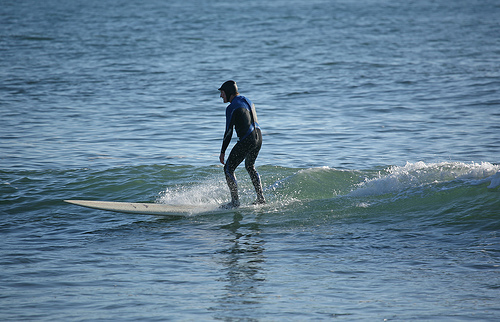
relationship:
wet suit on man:
[212, 77, 273, 208] [212, 74, 270, 209]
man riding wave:
[212, 74, 270, 209] [243, 156, 499, 217]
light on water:
[194, 216, 306, 262] [3, 1, 499, 320]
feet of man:
[216, 195, 268, 210] [212, 74, 270, 209]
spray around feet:
[159, 185, 225, 200] [216, 195, 268, 210]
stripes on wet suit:
[237, 98, 260, 137] [212, 77, 273, 208]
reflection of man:
[217, 209, 266, 295] [212, 74, 270, 209]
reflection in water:
[217, 209, 266, 295] [3, 1, 499, 320]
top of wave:
[390, 157, 497, 188] [243, 156, 499, 217]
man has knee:
[212, 74, 270, 209] [221, 163, 233, 176]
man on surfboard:
[212, 74, 270, 209] [56, 195, 275, 218]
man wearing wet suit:
[212, 74, 270, 209] [212, 77, 273, 208]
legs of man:
[221, 137, 266, 207] [212, 74, 270, 209]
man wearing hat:
[212, 74, 270, 209] [221, 78, 243, 99]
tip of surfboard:
[61, 197, 76, 203] [56, 195, 275, 218]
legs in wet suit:
[221, 137, 266, 207] [212, 77, 273, 208]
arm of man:
[216, 110, 234, 161] [212, 74, 270, 209]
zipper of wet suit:
[244, 97, 256, 119] [212, 77, 273, 208]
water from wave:
[3, 1, 499, 320] [243, 156, 499, 217]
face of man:
[219, 91, 228, 103] [212, 74, 270, 209]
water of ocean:
[3, 1, 499, 320] [3, 2, 479, 184]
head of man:
[215, 77, 240, 106] [212, 74, 270, 209]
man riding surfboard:
[212, 74, 270, 209] [56, 195, 275, 218]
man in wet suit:
[212, 74, 270, 209] [212, 77, 273, 208]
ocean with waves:
[3, 2, 479, 184] [102, 155, 499, 229]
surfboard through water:
[56, 195, 275, 218] [3, 1, 499, 320]